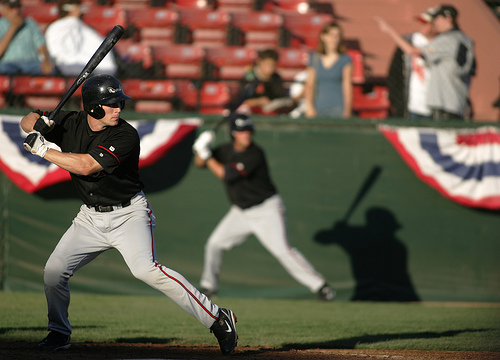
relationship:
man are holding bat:
[19, 68, 237, 358] [21, 23, 124, 151]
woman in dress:
[282, 5, 372, 159] [296, 9, 389, 139]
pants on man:
[3, 179, 224, 339] [20, 45, 260, 357]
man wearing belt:
[13, 61, 237, 358] [69, 188, 149, 222]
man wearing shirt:
[19, 68, 237, 358] [19, 107, 180, 206]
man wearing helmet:
[19, 68, 237, 358] [71, 72, 137, 135]